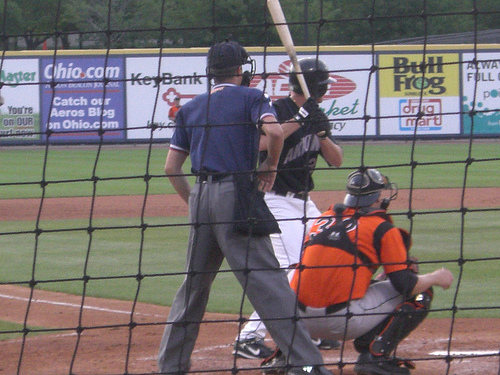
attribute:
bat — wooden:
[268, 3, 324, 116]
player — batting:
[235, 59, 345, 360]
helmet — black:
[292, 64, 338, 90]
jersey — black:
[268, 99, 331, 194]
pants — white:
[233, 187, 337, 338]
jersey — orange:
[296, 204, 411, 299]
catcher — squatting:
[304, 169, 446, 359]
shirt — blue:
[167, 89, 277, 172]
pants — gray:
[157, 175, 320, 372]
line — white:
[7, 284, 165, 331]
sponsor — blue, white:
[42, 61, 123, 91]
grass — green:
[21, 142, 490, 183]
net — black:
[1, 1, 498, 371]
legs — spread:
[160, 225, 320, 371]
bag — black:
[232, 181, 290, 231]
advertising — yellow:
[380, 55, 457, 102]